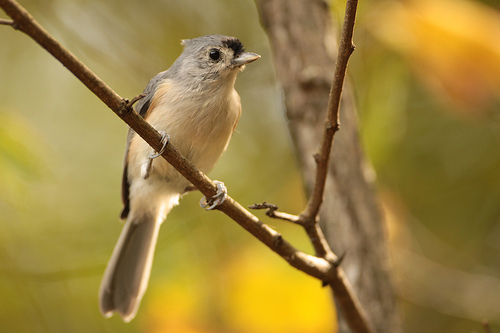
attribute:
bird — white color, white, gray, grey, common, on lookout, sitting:
[91, 31, 267, 326]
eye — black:
[211, 46, 227, 66]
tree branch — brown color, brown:
[0, 0, 371, 332]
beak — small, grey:
[230, 51, 264, 67]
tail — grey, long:
[97, 207, 173, 322]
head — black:
[174, 28, 268, 90]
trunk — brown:
[249, 2, 397, 330]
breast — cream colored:
[150, 94, 235, 194]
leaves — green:
[349, 52, 490, 278]